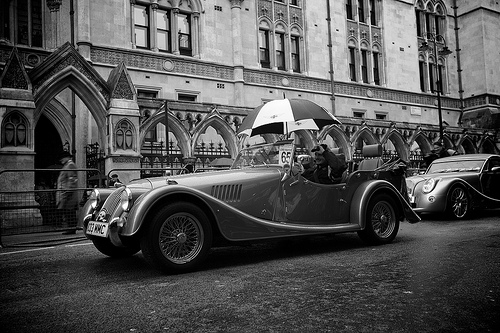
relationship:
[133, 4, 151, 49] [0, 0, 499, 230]
window on building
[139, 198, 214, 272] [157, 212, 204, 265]
wheel has a rims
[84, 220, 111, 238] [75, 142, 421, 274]
license plate on car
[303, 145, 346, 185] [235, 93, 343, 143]
man holding umbrella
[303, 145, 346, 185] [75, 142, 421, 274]
man driving car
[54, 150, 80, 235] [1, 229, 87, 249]
man on sidewalk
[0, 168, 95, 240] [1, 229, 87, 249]
barricade on sidewalk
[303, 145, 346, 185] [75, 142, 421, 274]
man in car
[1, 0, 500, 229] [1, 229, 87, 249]
arches above sidewalk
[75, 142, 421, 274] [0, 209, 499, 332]
car on road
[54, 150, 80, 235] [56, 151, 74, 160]
man wearing hat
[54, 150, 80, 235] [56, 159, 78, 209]
man wearing coat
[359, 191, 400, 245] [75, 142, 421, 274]
wheel on car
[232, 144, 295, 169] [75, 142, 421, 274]
windshield on car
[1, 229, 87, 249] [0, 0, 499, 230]
sidewalk in front of building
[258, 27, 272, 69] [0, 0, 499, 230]
window on building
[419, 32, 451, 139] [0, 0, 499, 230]
street lamp in front of building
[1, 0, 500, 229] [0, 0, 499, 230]
arches on building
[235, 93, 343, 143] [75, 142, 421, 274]
umbrella in car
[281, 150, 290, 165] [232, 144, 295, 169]
65 in windshield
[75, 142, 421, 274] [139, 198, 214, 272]
car has a wheel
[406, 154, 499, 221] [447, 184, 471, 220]
car has a wheel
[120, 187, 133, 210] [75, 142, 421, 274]
headlight on car